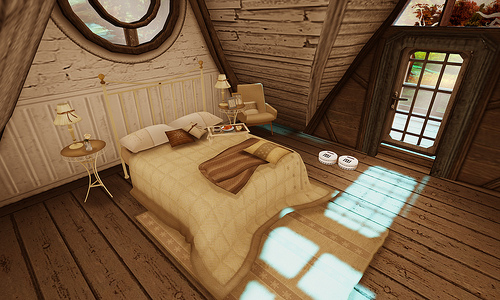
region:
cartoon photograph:
[7, 16, 486, 298]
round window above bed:
[65, 0, 180, 72]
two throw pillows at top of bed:
[170, 121, 206, 158]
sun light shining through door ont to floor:
[255, 155, 416, 292]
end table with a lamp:
[52, 74, 109, 210]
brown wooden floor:
[48, 215, 130, 288]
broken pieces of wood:
[293, 5, 313, 54]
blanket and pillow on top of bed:
[212, 130, 284, 200]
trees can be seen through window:
[407, 3, 499, 25]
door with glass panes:
[377, 45, 464, 157]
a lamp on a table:
[36, 80, 107, 156]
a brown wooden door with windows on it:
[370, 42, 495, 162]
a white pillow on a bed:
[120, 115, 182, 155]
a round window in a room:
[57, 0, 209, 75]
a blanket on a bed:
[135, 110, 341, 275]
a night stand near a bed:
[45, 130, 120, 211]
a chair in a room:
[231, 75, 293, 127]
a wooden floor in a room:
[55, 186, 160, 287]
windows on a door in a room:
[382, 65, 452, 140]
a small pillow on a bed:
[245, 125, 307, 174]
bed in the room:
[112, 58, 309, 235]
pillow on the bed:
[122, 118, 172, 163]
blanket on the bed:
[153, 140, 260, 233]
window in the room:
[368, 39, 483, 154]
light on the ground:
[318, 172, 421, 259]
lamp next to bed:
[48, 97, 103, 170]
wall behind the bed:
[114, 50, 194, 111]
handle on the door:
[381, 82, 416, 117]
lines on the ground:
[0, 222, 141, 297]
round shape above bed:
[50, 5, 206, 71]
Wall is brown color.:
[10, 21, 290, 296]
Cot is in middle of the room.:
[112, 107, 319, 277]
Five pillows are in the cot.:
[119, 100, 281, 187]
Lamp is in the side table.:
[27, 74, 104, 194]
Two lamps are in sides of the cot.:
[41, 83, 273, 165]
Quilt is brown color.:
[123, 138, 285, 263]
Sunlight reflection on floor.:
[278, 150, 433, 298]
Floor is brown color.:
[33, 228, 138, 288]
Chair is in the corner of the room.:
[231, 78, 291, 149]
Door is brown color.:
[359, 38, 469, 167]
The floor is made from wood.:
[50, 253, 134, 291]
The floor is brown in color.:
[45, 243, 155, 290]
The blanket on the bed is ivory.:
[164, 157, 191, 187]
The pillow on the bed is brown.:
[165, 128, 191, 145]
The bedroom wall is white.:
[93, 97, 142, 119]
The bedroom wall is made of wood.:
[26, 132, 51, 177]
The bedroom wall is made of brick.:
[50, 57, 83, 80]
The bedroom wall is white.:
[56, 60, 93, 80]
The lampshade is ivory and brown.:
[53, 101, 77, 128]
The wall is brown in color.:
[471, 128, 489, 173]